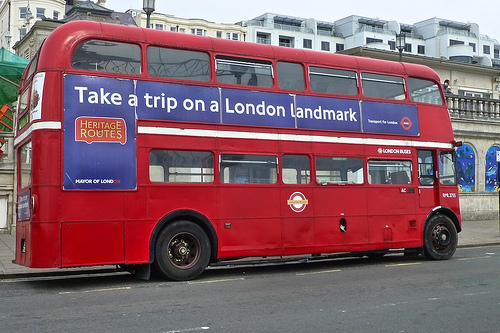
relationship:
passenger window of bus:
[147, 147, 213, 183] [16, 22, 463, 274]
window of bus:
[215, 155, 285, 185] [16, 22, 463, 274]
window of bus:
[278, 151, 313, 183] [16, 22, 463, 274]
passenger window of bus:
[316, 156, 364, 184] [16, 22, 463, 274]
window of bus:
[370, 161, 410, 188] [16, 22, 463, 274]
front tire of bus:
[421, 214, 459, 261] [9, 21, 463, 282]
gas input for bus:
[337, 212, 348, 238] [9, 21, 463, 282]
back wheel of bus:
[154, 219, 213, 282] [16, 22, 463, 274]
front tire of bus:
[421, 214, 459, 261] [16, 22, 463, 274]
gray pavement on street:
[321, 268, 446, 321] [3, 208, 497, 327]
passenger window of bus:
[309, 63, 357, 95] [16, 22, 463, 274]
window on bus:
[307, 64, 361, 98] [16, 22, 463, 274]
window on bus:
[359, 73, 406, 100] [9, 21, 486, 288]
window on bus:
[405, 71, 445, 103] [16, 22, 463, 274]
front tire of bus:
[421, 210, 461, 262] [16, 22, 463, 274]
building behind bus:
[421, 18, 498, 79] [16, 22, 463, 274]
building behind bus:
[346, 12, 426, 55] [16, 22, 463, 274]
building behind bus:
[268, 14, 344, 51] [16, 22, 463, 274]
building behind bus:
[176, 12, 251, 39] [16, 22, 463, 274]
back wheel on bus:
[152, 217, 215, 282] [9, 21, 486, 288]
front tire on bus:
[421, 214, 459, 261] [16, 22, 463, 274]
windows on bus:
[60, 24, 465, 124] [9, 21, 486, 288]